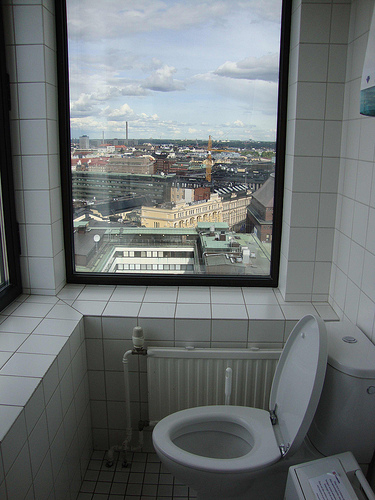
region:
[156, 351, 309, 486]
white toilet in bathroom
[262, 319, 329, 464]
white lid on toilet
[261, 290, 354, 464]
toilet lid is raised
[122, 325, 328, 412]
white radiator near toilet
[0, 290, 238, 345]
white tile near toilet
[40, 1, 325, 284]
black frame on window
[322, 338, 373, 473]
white tank behind toilet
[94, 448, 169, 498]
grey tile on floor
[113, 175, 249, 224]
large tan building outside window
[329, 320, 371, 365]
flush on top of toilet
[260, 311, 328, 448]
toilet seat is up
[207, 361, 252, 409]
brush for cleaning the toilet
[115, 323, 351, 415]
radiator next to toilet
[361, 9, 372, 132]
air refreshener on the wall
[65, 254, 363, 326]
sill along the window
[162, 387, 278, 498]
toilet is white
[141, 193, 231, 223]
building is a mustard yellow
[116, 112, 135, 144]
tall building in the back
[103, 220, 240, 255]
roof of the building is green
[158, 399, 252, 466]
toilet seat is lowered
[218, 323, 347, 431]
white toilet seat cover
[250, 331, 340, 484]
seat cover is raised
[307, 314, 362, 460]
white tank behind toilet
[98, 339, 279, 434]
white radiator near toilet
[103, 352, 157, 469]
white pipe on radiator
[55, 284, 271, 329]
white tile on walls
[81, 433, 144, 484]
white tile on floor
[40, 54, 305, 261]
black frame around window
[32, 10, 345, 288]
white tile on wall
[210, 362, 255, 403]
white plunger behind toilet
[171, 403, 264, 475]
toilet has white seat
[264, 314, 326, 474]
white lid is raised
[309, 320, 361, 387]
white bin behind toilet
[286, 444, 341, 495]
white first aid kit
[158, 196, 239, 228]
large tan building in window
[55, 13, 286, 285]
city through bathroom window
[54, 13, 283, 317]
white tile ledge under window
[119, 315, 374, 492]
radiator behind toilet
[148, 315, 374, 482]
toilet lid is up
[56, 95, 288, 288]
window has black frame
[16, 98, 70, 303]
white tile wall to left of window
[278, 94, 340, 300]
white tile wall to right of window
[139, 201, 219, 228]
yellow building through window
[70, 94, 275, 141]
partly cloudy sky through window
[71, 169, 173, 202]
parking garage through window